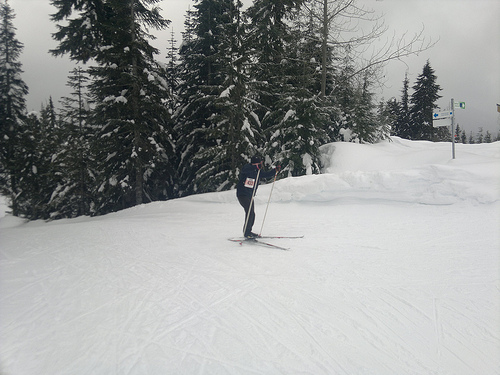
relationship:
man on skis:
[238, 151, 263, 237] [213, 208, 359, 306]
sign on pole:
[429, 88, 450, 122] [437, 90, 467, 154]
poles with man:
[248, 181, 287, 232] [238, 151, 263, 237]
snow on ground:
[365, 199, 476, 298] [109, 266, 407, 365]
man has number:
[202, 139, 295, 249] [239, 170, 284, 200]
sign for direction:
[429, 88, 450, 122] [356, 83, 439, 169]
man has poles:
[238, 151, 263, 237] [248, 181, 287, 232]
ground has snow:
[109, 266, 407, 365] [365, 199, 476, 298]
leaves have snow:
[76, 65, 130, 148] [365, 199, 476, 298]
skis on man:
[213, 208, 359, 306] [238, 151, 263, 237]